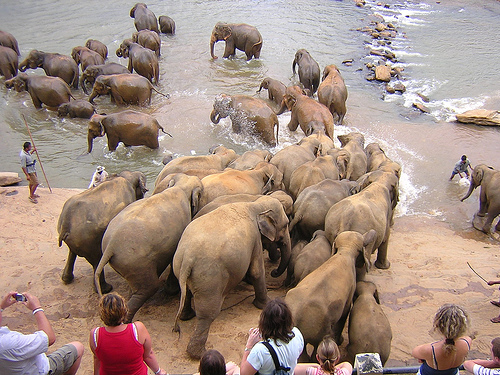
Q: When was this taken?
A: Daytime.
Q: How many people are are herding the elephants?
A: 2.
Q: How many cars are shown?
A: 0.